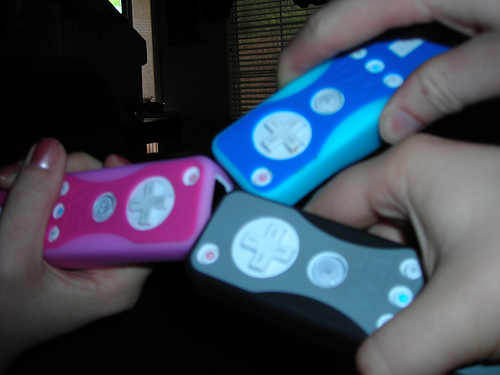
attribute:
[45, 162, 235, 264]
controller — pink, black, for video game, white, gray, for playing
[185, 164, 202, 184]
button — power button, red, white, on off button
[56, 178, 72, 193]
button — lit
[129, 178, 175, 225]
button — white, on top, directional key, round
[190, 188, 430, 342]
controller — grey, gray, black, tan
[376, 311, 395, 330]
button — white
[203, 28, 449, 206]
controller — blue, white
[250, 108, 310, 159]
button — white, large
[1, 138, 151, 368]
hand — female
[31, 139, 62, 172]
pink nail polish — light pink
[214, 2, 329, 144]
window — letting light in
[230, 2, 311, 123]
blinds — slated, wooden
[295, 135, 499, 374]
hand — human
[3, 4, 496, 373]
room — dark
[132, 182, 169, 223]
cross — white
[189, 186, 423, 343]
casing — black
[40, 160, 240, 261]
casing — pink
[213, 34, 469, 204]
casing — blue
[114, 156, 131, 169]
nail polish — pink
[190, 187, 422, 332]
surface — tan